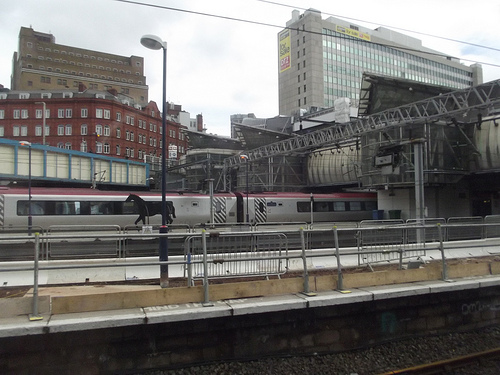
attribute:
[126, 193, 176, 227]
horse — black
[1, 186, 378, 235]
train — stopped, passing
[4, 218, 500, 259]
tracks — railroad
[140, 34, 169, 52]
light — street, top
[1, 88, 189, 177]
building — brick, big, red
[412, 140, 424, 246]
pipe — steel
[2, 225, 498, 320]
fence — long, iron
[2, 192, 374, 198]
top — red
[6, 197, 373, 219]
side — silver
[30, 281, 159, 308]
platform — empty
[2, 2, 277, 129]
sky — gray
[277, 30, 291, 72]
advertisement — yellow